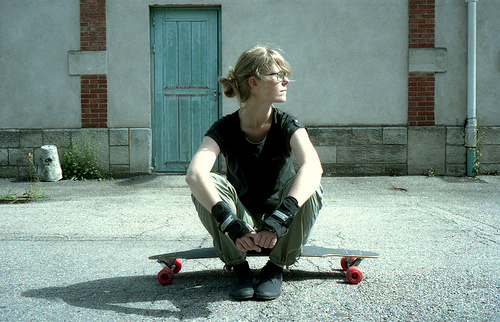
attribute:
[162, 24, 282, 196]
door — blue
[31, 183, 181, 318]
cement — cracked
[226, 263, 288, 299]
shoes — black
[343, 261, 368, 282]
wheels — red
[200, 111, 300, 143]
sleeves — short